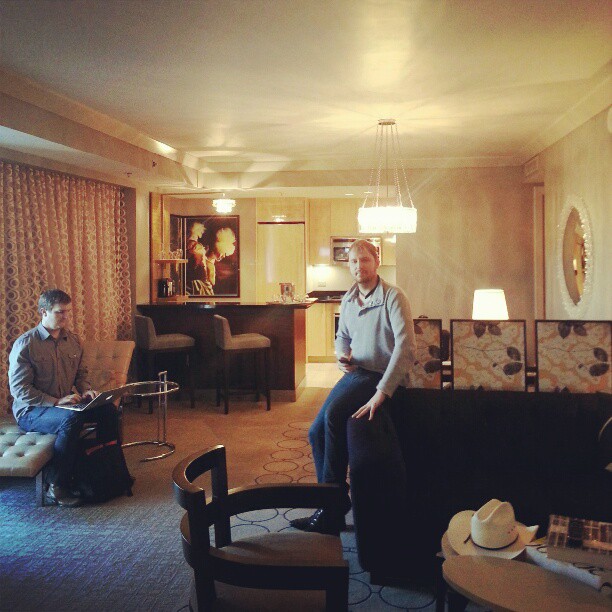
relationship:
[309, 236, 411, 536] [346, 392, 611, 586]
man sitting on chair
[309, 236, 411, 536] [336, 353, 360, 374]
man holding phone